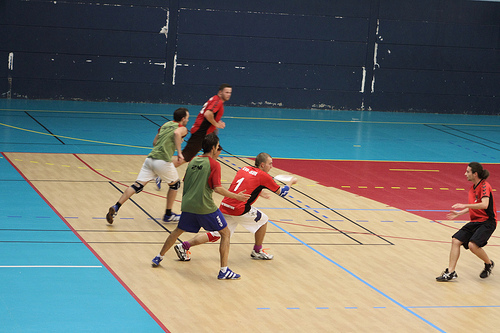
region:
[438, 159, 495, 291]
A man running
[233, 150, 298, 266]
A man throwing a frisbee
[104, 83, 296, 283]
A group of athletes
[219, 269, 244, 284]
Blue and white sneakers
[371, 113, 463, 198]
The floor is blue and white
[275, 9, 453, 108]
Blue boards stacked up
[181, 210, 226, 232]
Blue shorts on a player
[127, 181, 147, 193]
Man is wearing knee pads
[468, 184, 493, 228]
Player wearing red jersey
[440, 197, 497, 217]
A man's arms are outstretched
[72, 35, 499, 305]
people playing ultimate Frisbe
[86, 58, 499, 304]
group of five people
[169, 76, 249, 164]
guy running down the court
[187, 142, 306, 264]
man throwing a Frisbee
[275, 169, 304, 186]
round white Frisbee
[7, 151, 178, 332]
dark red line on the court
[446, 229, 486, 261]
knees are bent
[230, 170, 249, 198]
white number on the back of the jersey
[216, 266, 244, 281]
blue and white shoe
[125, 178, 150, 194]
black knee pad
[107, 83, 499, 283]
Five guys are playing basketball.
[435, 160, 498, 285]
A basketball player is wearing a red and black uniform.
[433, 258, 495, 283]
A basketball player is wearing black and white shoes.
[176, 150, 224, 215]
A basketball player is wearing a green and red top.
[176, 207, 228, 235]
A basketball player is wearing blue and white colored shorts.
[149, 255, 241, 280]
a basketball player is wearing blue and white shorts.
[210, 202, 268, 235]
A basketball player is wearing white and black shorts.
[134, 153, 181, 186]
A basketball player is wearing white shorts.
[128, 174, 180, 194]
A basketball player is wearing knee guards.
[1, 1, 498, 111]
The color of a wall is mostly blue.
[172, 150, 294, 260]
a man throwing a frisbee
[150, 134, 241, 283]
a man playing frisbee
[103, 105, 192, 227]
a man playing frisbee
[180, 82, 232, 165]
a man playing frisbee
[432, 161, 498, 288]
a man playing frisbee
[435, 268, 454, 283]
a black athletic shoe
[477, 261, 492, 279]
a black athletic shoe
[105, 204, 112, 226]
a black athletic shoe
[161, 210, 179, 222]
a black athletic shoe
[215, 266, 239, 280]
a blue and white athletic shoe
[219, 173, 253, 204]
1 on the back of guy's shirt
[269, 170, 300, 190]
guy is holding a frisbee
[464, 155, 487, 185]
guy has a ponytail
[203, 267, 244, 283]
three white stripes on his shoe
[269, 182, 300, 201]
guy is wearing elbow pad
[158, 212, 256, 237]
guy's shorts are blue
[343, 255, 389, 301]
aqua line on the floor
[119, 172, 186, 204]
guy is wearing knee pads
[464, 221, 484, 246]
guy is wearing black shorts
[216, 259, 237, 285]
guy's tennis shoe is blue